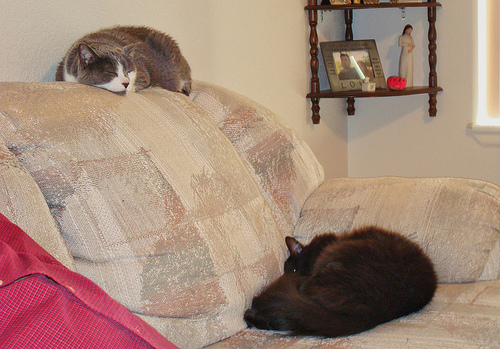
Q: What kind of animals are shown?
A: Cats.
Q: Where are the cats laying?
A: On the couch.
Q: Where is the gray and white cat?
A: On top of the couch.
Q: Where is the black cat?
A: On the seat of the couch.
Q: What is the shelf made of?
A: Wood.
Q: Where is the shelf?
A: In the corner.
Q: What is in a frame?
A: A picture on the shelf.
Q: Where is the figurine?
A: On the shelf.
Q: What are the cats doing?
A: Sleeping.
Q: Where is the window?
A: To the right of the shelf.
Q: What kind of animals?
A: Cats.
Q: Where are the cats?
A: On the couch.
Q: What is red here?
A: A blanket.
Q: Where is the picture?
A: On the shelf.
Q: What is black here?
A: Cat.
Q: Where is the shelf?
A: In the corner.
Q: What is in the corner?
A: A shelf.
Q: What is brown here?
A: The shelf.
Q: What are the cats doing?
A: Sleeping.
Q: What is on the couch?
A: Cats.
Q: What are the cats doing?
A: Napping.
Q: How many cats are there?
A: Two.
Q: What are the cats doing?
A: Laying.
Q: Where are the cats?
A: The couch.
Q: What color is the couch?
A: White.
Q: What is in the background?
A: A picture.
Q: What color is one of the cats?
A: Black.